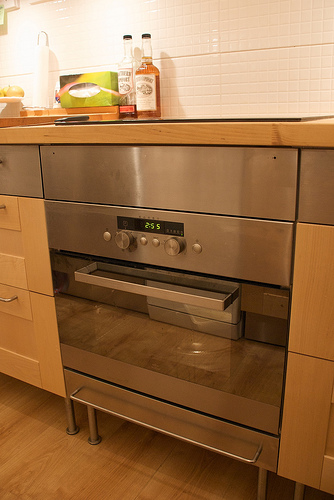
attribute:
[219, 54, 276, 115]
tile — white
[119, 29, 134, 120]
bottle — wiskey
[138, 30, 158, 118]
bottle — wiskey